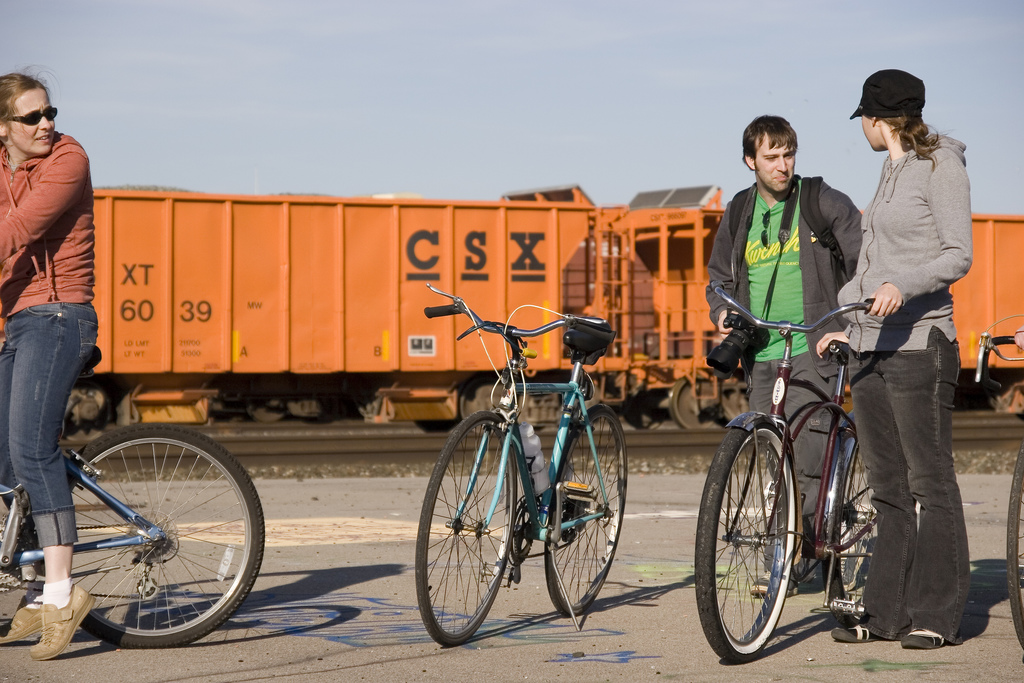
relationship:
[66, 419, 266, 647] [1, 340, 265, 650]
tire on bike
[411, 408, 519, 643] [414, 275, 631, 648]
tire on bike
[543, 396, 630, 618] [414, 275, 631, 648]
tire on bike